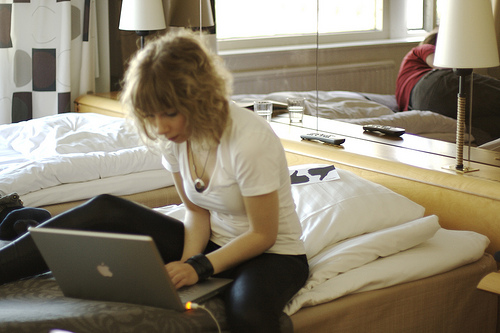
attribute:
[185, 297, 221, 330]
power cord — is glowing, is yellow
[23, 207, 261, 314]
laptop — is silver, is mac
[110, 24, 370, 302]
woman — is plain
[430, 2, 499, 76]
shade — white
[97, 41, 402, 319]
woman — is blonde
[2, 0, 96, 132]
drapes — white, brown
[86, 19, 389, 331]
woman — wearing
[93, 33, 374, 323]
woman — wearing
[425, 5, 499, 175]
lamp — white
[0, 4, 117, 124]
curtain — is black, is white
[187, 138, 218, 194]
necklace — is silver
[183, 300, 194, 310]
light — orange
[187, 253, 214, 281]
leather — black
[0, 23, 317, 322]
woman — sitting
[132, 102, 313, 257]
shirt — is white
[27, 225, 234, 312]
macbook — apple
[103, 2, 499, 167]
mirror — behind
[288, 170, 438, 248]
pillow — is white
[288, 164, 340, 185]
brochure — black, white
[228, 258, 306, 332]
pants — are black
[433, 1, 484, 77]
lampshade — is beige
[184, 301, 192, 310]
light — is orange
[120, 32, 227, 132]
hair — is blonde, is messy, is dark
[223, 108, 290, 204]
shirt — is white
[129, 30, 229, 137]
hair — is curly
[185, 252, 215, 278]
wristband — is black